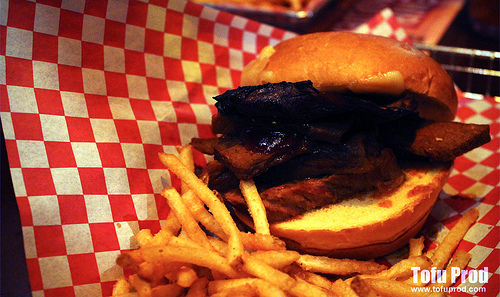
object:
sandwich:
[200, 31, 462, 255]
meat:
[219, 90, 497, 187]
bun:
[241, 174, 439, 256]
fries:
[157, 149, 244, 267]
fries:
[427, 209, 481, 270]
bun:
[232, 28, 458, 121]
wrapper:
[6, 19, 498, 295]